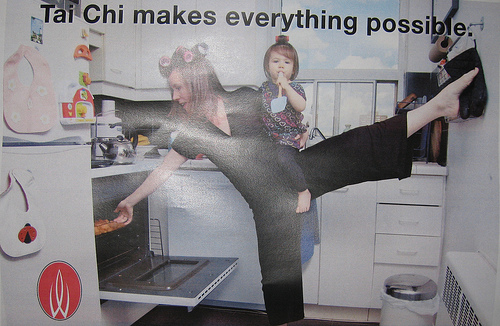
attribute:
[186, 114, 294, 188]
shirt — black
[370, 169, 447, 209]
cabinet drawer — white 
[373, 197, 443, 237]
cabinet drawer — white 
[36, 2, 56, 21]
letter — black 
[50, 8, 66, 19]
letter — black , print style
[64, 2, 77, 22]
letter — black , print style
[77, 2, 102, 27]
letter — black , print style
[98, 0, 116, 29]
letter — black , print style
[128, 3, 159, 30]
letter — black , print style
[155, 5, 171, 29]
letter — black , print style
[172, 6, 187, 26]
letter — black , print style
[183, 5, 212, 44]
letter — print style, black 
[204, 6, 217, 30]
letter — black , print style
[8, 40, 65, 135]
bib — white , pink 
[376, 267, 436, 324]
trash can — white 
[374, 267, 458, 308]
silver lid — silver 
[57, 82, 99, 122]
barn toy — little , red 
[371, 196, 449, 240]
white drawer — white , partially opened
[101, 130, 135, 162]
tea kettle — silver 